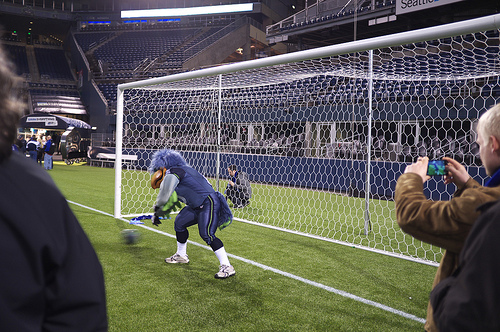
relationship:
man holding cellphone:
[384, 84, 499, 316] [416, 144, 460, 184]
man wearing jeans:
[43, 136, 56, 172] [42, 151, 53, 170]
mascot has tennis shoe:
[124, 143, 242, 284] [164, 251, 191, 265]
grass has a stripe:
[82, 200, 423, 330] [244, 259, 416, 330]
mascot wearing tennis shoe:
[146, 147, 238, 279] [209, 254, 243, 282]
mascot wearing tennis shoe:
[146, 147, 238, 279] [164, 246, 182, 263]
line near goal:
[127, 212, 426, 326] [115, 0, 498, 330]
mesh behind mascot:
[254, 100, 382, 183] [135, 139, 250, 289]